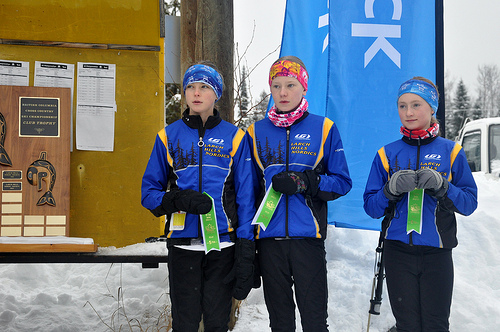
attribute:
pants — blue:
[382, 238, 454, 330]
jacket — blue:
[371, 138, 456, 233]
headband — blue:
[396, 82, 436, 102]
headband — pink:
[259, 58, 309, 92]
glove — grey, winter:
[421, 165, 464, 200]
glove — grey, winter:
[377, 168, 430, 198]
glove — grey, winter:
[261, 150, 331, 197]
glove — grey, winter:
[158, 182, 239, 222]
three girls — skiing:
[148, 58, 489, 233]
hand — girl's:
[414, 162, 441, 192]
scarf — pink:
[269, 98, 307, 125]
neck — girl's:
[275, 109, 301, 122]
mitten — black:
[166, 182, 220, 222]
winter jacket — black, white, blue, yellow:
[139, 113, 249, 250]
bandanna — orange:
[257, 45, 333, 91]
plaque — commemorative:
[2, 85, 70, 237]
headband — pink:
[265, 62, 317, 95]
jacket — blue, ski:
[350, 131, 475, 238]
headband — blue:
[175, 53, 242, 80]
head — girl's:
[153, 52, 240, 136]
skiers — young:
[143, 59, 255, 329]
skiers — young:
[238, 54, 351, 326]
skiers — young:
[364, 75, 468, 322]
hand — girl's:
[175, 187, 212, 214]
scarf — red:
[401, 121, 440, 138]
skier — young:
[137, 58, 251, 329]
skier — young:
[239, 51, 355, 330]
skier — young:
[359, 70, 479, 330]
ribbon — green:
[191, 190, 227, 256]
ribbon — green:
[250, 178, 285, 234]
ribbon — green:
[403, 183, 427, 237]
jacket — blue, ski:
[246, 113, 356, 243]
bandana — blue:
[184, 63, 226, 96]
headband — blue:
[178, 60, 223, 97]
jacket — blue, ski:
[137, 106, 252, 250]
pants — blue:
[250, 232, 330, 329]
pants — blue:
[160, 230, 245, 330]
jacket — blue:
[239, 100, 354, 240]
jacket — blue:
[139, 110, 258, 253]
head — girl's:
[264, 57, 311, 127]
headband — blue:
[395, 79, 442, 115]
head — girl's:
[394, 72, 441, 132]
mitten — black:
[230, 232, 262, 299]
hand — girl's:
[229, 235, 259, 305]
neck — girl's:
[397, 119, 448, 147]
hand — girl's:
[263, 165, 321, 200]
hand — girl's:
[149, 181, 215, 219]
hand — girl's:
[269, 164, 321, 198]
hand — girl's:
[382, 158, 445, 200]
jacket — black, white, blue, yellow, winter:
[238, 110, 353, 249]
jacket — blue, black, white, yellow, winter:
[359, 129, 482, 251]